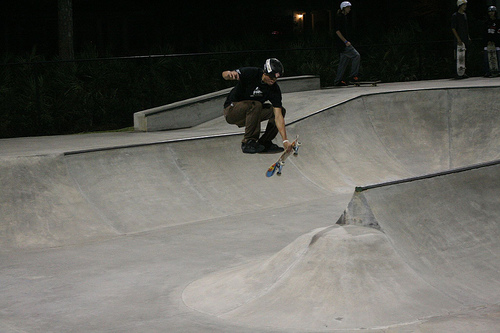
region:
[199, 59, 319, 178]
Person on a skate board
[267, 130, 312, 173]
skateboard in the air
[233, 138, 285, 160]
person wearing black shoes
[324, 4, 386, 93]
person in a skateboard park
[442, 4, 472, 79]
person in a skateboard park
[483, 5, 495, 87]
person in a skateboard park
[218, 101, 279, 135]
man wearing brown pants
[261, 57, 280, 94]
man wearing a black helmet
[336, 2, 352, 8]
man wearing a white helmet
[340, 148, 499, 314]
ramp in the skate park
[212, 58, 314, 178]
man is on skateboard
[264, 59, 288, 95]
black and white helmet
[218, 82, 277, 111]
black and white shirt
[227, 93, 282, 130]
man has brown pants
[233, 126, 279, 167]
man has black shoes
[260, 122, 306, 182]
blue and brown board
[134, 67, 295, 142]
grey ramp behind man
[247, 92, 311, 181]
man is holding skateboard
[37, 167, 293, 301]
grey concrete in skate park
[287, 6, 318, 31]
orange light behind man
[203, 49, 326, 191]
man on a skateboard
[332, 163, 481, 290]
top of the ramp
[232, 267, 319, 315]
lighter part of ramp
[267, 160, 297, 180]
wheels on the skateboard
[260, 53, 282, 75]
helmet on the head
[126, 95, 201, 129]
smaller part of ramp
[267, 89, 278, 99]
the shirt is black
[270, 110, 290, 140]
leg on the man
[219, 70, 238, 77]
arm on the man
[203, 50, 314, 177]
person on a stake board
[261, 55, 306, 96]
person wearing a black helmet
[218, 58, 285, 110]
person wearing a black tee shirt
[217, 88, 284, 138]
person wearing brown pants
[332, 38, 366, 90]
person wearing gray pants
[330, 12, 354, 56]
person wearing black shirts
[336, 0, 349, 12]
person wearing a white helmet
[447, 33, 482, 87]
person holding a white skate board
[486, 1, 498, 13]
person wearing a gray helmet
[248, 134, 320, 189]
skate board in the sky